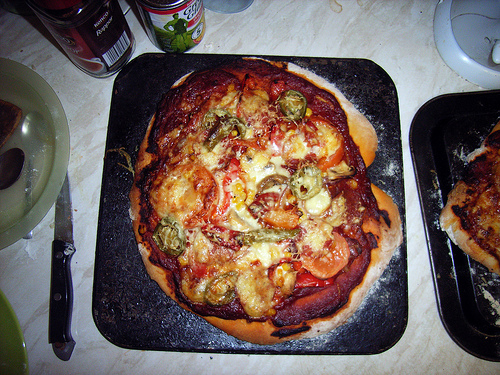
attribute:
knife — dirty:
[49, 169, 77, 361]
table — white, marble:
[2, 0, 499, 375]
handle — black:
[46, 243, 74, 359]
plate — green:
[1, 292, 30, 372]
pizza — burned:
[128, 59, 399, 340]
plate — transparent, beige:
[1, 58, 68, 249]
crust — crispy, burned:
[134, 53, 402, 344]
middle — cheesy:
[197, 108, 320, 279]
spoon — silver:
[0, 148, 27, 192]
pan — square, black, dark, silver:
[91, 47, 407, 362]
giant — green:
[164, 12, 193, 49]